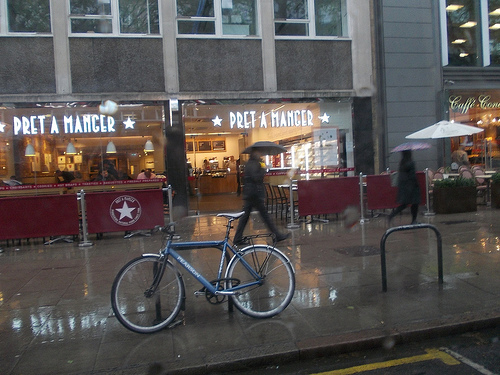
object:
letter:
[230, 112, 236, 129]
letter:
[237, 112, 244, 128]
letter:
[244, 112, 249, 128]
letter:
[260, 110, 267, 128]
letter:
[271, 112, 279, 127]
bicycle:
[112, 211, 295, 333]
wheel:
[227, 246, 295, 318]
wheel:
[111, 255, 184, 334]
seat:
[216, 211, 245, 220]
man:
[233, 149, 288, 246]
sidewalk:
[0, 195, 499, 374]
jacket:
[241, 156, 269, 198]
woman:
[383, 148, 420, 225]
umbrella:
[389, 141, 432, 153]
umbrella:
[241, 141, 288, 155]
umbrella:
[404, 120, 484, 139]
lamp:
[106, 142, 116, 153]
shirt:
[137, 172, 158, 179]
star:
[212, 115, 223, 127]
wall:
[297, 176, 361, 215]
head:
[251, 149, 263, 161]